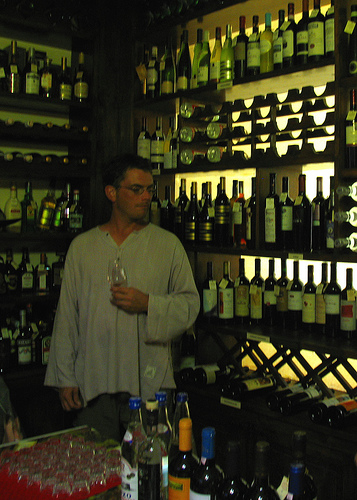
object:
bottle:
[114, 385, 315, 498]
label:
[279, 285, 310, 322]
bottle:
[214, 256, 236, 324]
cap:
[179, 417, 192, 429]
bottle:
[312, 176, 327, 256]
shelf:
[0, 22, 347, 436]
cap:
[142, 397, 158, 410]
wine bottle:
[213, 173, 230, 246]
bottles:
[322, 171, 337, 249]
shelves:
[196, 7, 329, 295]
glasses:
[80, 475, 90, 487]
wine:
[200, 181, 214, 246]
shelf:
[181, 239, 356, 262]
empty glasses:
[103, 256, 130, 292]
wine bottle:
[245, 176, 253, 245]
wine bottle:
[263, 170, 281, 247]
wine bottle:
[310, 177, 321, 246]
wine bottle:
[262, 258, 276, 325]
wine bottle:
[287, 260, 303, 328]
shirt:
[55, 209, 188, 374]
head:
[93, 151, 162, 223]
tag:
[140, 362, 158, 384]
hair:
[100, 152, 159, 192]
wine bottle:
[293, 173, 312, 251]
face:
[118, 169, 156, 216]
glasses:
[120, 182, 156, 193]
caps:
[127, 393, 144, 406]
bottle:
[200, 179, 216, 247]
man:
[43, 150, 200, 439]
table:
[2, 422, 323, 497]